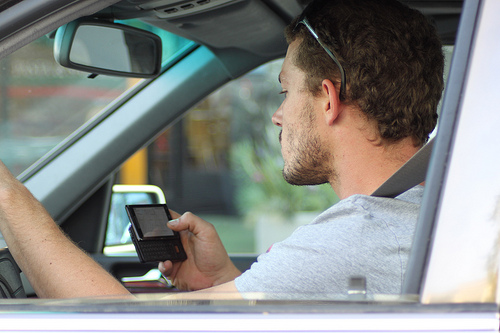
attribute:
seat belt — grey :
[370, 135, 435, 197]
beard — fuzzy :
[284, 137, 324, 193]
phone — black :
[124, 199, 187, 264]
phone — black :
[125, 201, 188, 270]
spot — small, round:
[354, 205, 390, 227]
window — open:
[3, 6, 497, 321]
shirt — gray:
[231, 185, 424, 295]